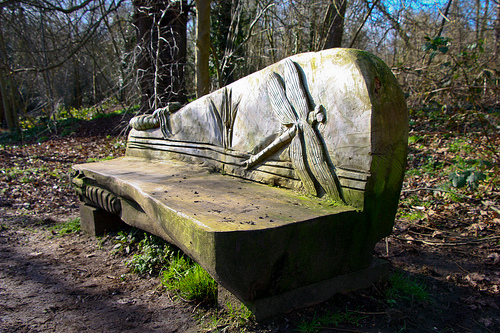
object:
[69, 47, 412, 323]
bench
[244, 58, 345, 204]
dragonfly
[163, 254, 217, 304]
grass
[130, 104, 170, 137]
bug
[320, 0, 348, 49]
trees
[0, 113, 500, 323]
ground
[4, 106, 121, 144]
bush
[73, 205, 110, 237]
leg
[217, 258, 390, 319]
leg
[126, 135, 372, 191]
lines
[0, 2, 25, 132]
tree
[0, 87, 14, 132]
trunk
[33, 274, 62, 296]
mud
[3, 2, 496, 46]
sky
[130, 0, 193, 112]
tree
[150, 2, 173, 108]
branches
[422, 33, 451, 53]
leaves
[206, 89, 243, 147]
cattails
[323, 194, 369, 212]
moss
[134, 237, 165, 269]
grass+weeds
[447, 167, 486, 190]
leaves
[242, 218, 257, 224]
rock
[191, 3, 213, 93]
trunk